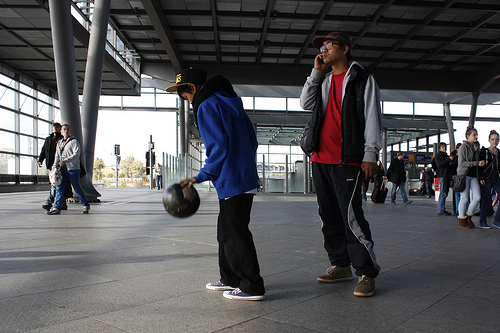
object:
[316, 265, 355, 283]
shoe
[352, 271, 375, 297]
shoe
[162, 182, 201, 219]
ball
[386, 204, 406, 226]
ground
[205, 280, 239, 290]
shoe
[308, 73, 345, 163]
t-shirt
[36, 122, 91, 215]
people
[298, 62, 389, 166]
sweatshirt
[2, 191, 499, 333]
floor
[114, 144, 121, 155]
sign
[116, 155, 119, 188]
post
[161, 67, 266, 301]
boy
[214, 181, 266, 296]
pants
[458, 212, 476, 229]
boots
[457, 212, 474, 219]
beige fleece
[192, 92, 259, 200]
jacket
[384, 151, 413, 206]
person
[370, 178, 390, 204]
luggage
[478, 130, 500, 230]
girl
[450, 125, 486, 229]
girl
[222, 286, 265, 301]
shoes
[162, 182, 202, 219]
blackish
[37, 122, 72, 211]
man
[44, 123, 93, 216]
man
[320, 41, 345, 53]
glasses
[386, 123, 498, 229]
people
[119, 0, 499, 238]
background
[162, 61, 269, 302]
boy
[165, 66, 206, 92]
baseball cap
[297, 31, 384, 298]
boy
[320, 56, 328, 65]
cell phone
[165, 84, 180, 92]
bill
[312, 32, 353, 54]
hat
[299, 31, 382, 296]
male